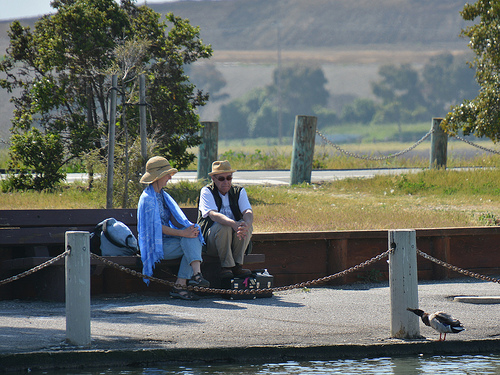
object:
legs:
[162, 237, 192, 288]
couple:
[135, 155, 253, 301]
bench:
[0, 207, 264, 275]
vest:
[196, 182, 251, 254]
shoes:
[188, 272, 210, 287]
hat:
[139, 156, 178, 184]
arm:
[201, 192, 235, 226]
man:
[196, 160, 255, 280]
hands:
[236, 221, 249, 240]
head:
[211, 161, 233, 192]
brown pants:
[162, 237, 204, 279]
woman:
[137, 156, 210, 299]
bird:
[406, 307, 466, 342]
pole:
[429, 118, 448, 168]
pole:
[289, 115, 318, 184]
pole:
[198, 122, 219, 179]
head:
[145, 156, 172, 185]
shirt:
[155, 192, 172, 238]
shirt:
[197, 182, 252, 255]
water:
[8, 357, 498, 374]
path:
[0, 276, 499, 350]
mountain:
[1, 1, 487, 116]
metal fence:
[89, 249, 396, 295]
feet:
[218, 269, 234, 279]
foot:
[192, 277, 209, 285]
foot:
[169, 288, 192, 298]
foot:
[235, 269, 252, 277]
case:
[221, 275, 273, 300]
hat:
[208, 160, 236, 176]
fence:
[316, 129, 432, 169]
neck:
[421, 312, 428, 321]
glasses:
[214, 175, 232, 181]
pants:
[205, 223, 254, 267]